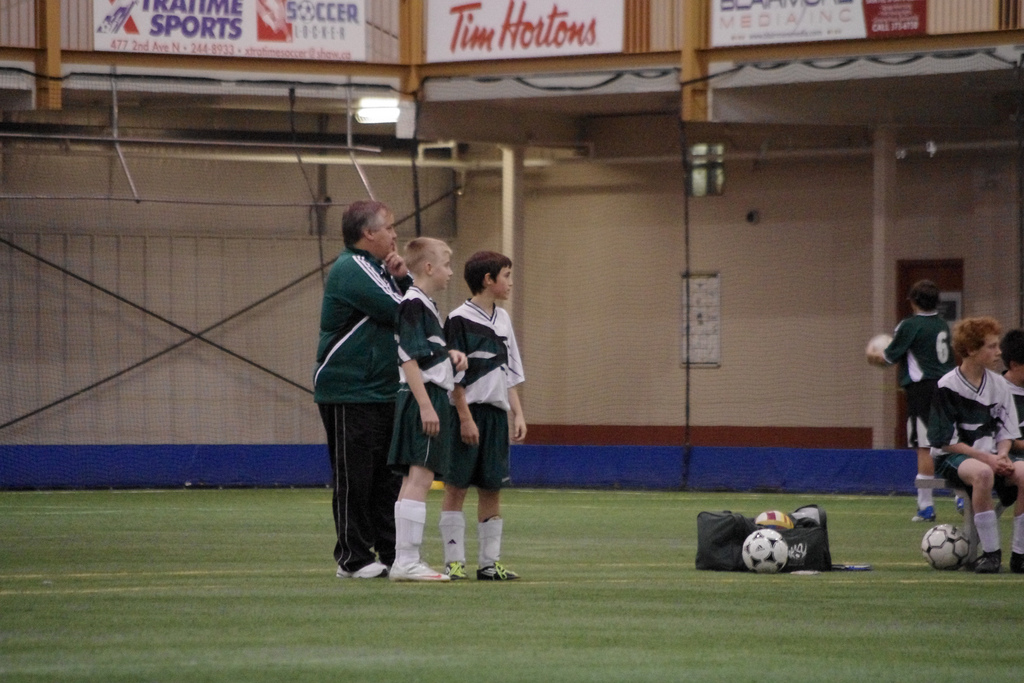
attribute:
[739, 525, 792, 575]
ball — white, black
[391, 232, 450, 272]
hair — blonde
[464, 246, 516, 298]
hair — brown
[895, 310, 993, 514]
boy — sitting, ginger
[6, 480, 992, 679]
grass — green, short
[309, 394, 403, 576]
pants — black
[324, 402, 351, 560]
stripes — thin, white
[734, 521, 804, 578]
soccer ball — black, white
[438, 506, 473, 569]
sock — white, long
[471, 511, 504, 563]
sock — white, long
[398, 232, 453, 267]
hair — blonde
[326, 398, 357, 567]
stripes — white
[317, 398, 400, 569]
pants — black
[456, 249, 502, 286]
hair — brown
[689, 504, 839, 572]
bag — black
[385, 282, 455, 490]
uniform — green, white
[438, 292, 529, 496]
uniform — green, white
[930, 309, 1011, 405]
hair — red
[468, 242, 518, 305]
hair — brown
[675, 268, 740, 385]
poster — white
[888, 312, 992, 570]
boy — sitting 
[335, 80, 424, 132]
light — on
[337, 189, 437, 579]
man — watching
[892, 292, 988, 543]
boy — blonde hair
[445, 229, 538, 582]
boy — dark hair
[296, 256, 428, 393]
shirt — green 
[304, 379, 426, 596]
pants — black athletic 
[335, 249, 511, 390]
shirt — white  , green 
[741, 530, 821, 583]
ball — soccer 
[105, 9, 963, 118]
signs — advertising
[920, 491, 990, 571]
ball — soccer 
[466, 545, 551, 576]
shoelaces — green 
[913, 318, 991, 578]
boy — red hair